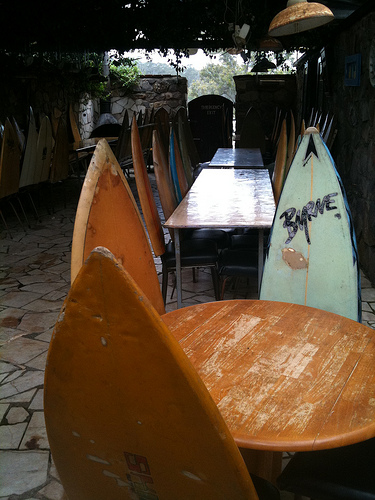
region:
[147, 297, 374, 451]
Round wooden cafe table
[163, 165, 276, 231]
Rectangular wooden cafe table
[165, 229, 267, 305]
Metal posts of table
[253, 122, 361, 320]
Broken surfboard tip made into chair back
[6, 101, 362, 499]
Cafe with chairs made from surfboards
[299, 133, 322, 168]
Painted emblem on tip of surfboard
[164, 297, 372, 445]
Scuffed wooden table top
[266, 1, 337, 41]
Lamp for cafe interior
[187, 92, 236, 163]
Gate entrance to cafe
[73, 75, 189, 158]
Stone wall of cafe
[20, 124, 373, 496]
the back rests are made from surf boards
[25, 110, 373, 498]
the backrests are surfboards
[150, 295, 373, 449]
the table top is scratched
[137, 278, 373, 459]
this table is round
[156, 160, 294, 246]
this table is long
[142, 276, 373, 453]
this table is made from wood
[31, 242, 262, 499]
this surfboard is yellow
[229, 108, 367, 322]
this surfboard is blue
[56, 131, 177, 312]
this board is white and yellow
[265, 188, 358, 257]
this decal says "Byrne"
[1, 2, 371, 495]
Shot of surfing-themed outdoors restaurant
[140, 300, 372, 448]
Scratched and scuffed wooden table top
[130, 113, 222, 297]
Chairs made from old surfboards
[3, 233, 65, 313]
Ground made of flagstone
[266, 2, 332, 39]
Hanging overhead lamp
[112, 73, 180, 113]
Exterior stone wall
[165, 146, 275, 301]
Two large dining tables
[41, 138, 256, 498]
Old surfboards fashioned into chairs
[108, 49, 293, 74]
View to the outside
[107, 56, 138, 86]
Green shrub on exterior stone wall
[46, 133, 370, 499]
surfboard chairs and table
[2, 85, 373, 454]
lots of seating at this restaurant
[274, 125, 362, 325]
white surfboard dining chair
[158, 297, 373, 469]
circular brown dining table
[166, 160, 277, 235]
rectangle brown dining table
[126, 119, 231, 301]
chairs with surfboards on them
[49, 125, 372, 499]
surfboard chairs next to table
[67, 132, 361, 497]
table is near surfboard chairs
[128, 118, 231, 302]
half a surfboard on the chair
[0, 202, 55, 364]
rock stones are on the ground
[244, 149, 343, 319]
white and blue board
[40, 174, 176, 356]
brown surfboard as chair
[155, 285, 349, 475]
table is light brown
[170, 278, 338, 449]
round and old table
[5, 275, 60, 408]
light grey stone floor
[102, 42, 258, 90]
grey sky in distance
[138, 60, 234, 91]
green trees in distance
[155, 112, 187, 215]
blue border on board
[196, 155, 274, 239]
light grey rectangular table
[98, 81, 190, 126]
stone wall outside room